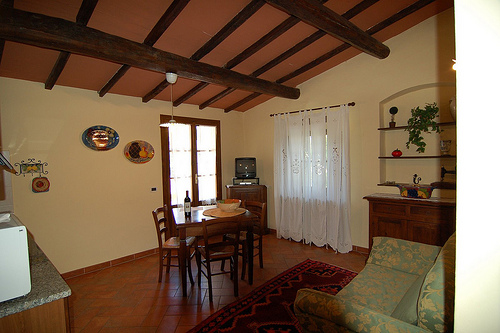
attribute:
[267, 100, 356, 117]
rod — long, slim, gold, curtain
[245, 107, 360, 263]
curtain — white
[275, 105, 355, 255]
curtain — white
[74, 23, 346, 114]
beam — wooden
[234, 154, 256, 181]
small television — black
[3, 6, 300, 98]
beam — wooden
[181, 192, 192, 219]
wine bottle — tall, green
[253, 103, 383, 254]
curtains — long, sheer, white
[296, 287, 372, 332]
arm — gold, green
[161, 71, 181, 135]
light — white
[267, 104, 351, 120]
rod — black